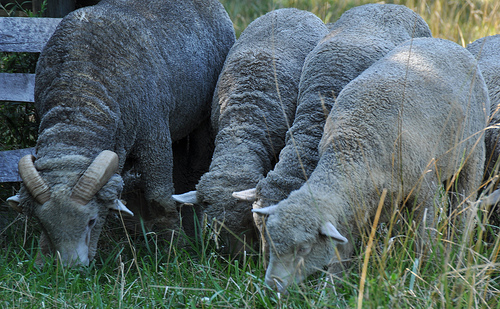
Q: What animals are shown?
A: Sheep.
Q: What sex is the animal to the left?
A: Male.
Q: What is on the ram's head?
A: Horns.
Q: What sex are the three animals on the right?
A: Female.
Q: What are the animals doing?
A: Eating grass.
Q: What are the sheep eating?
A: Grass.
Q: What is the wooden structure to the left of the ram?
A: A fence.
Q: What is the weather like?
A: Sunny.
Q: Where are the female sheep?
A: To the right of the ram.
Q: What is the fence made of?
A: Wood.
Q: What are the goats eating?
A: Grass.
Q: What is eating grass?
A: Goats.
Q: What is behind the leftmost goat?
A: A fence.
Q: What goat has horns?
A: The left one.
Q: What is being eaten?
A: Grass.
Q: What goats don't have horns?
A: All but one of them.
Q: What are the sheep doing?
A: Eating grass.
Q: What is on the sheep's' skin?
A: Fur.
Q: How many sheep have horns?
A: One.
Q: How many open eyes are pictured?
A: One.